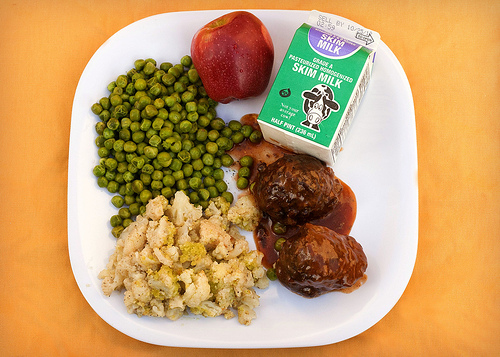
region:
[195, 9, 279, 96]
a red apple on white plate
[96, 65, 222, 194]
green peas on white plate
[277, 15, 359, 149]
a carton of skim milk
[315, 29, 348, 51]
the text skim milk on carton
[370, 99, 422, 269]
white plate with food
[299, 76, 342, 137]
drawing of cow on milk carton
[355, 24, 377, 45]
arrow pointing to right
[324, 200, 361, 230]
red sauce on white plate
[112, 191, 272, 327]
yellow chunk of food on plate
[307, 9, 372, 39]
expiration date information on milk carton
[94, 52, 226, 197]
lightly roasted green peas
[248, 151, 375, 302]
red glazed sauce on meatballs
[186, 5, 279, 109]
whole red apple on plate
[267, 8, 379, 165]
small skin mild carton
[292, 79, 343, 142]
black and white cow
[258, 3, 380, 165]
blue, green, and white milk carton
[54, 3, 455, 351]
smooth corner white plate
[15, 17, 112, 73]
orange table cloth under plate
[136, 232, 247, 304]
yellow well seasoned macaroni and cheese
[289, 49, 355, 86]
white letters on milk carton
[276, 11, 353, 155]
a box of skim milk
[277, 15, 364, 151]
a small carton of milk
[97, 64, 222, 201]
green peas on plate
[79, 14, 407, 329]
a plate of food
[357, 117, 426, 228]
a white plate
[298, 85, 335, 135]
picture of cow on milk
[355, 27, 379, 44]
an arrow pointing to the right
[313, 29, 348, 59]
the text skim milk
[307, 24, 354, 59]
purple portion of milk carton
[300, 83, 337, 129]
a black and white cartoon cow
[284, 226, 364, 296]
sauce covered meatball on a plate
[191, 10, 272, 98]
a red apple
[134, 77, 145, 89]
a single green pea on a plate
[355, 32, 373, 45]
a black arrow on a white background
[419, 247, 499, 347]
a section of orange tabletop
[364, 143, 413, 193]
an empty section of a white plate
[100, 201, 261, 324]
some home made macaroni and cheese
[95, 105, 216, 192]
a bunch of small green peas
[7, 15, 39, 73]
this is a table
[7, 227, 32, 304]
the table is wooden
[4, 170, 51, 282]
the table is orange in color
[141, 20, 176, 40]
this is a plate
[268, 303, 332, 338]
the plate is white in color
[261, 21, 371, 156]
this is a packet of milk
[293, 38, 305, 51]
the box is green in color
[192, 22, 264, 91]
this is an apple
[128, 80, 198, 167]
these are some peas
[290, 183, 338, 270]
this is some beef